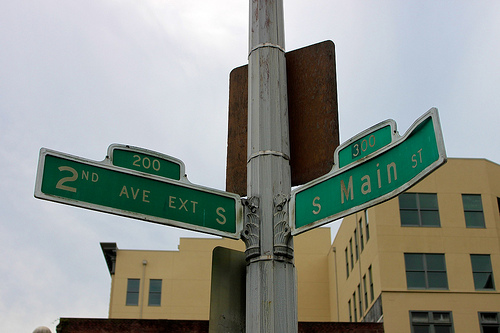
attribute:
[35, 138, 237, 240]
sign — green, 2nd ave ext s, 2nd avenue, 2nd ave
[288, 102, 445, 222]
sign — green, s main st, south main street, main st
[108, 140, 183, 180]
sign — 200, 200th block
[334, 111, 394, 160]
sign — 300, 300th block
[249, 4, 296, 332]
street pole — gray, patterned, skinny, grey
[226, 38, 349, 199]
street sign — brown, black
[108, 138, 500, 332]
building — tan, large, yellow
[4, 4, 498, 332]
sky — clear, blue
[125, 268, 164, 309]
windows — by themselves